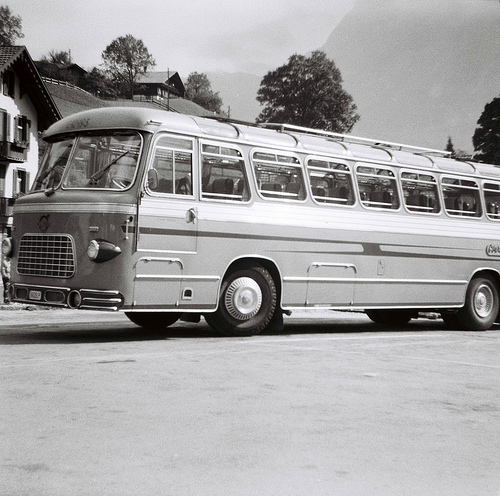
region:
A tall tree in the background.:
[256, 47, 361, 138]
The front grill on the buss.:
[15, 232, 77, 282]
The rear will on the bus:
[465, 275, 499, 333]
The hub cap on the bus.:
[224, 275, 263, 322]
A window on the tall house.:
[13, 112, 33, 151]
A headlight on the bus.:
[86, 239, 99, 263]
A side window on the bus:
[199, 137, 251, 204]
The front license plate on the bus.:
[27, 289, 43, 302]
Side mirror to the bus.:
[146, 170, 159, 190]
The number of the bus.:
[63, 117, 91, 128]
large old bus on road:
[1, 105, 498, 337]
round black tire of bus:
[211, 260, 278, 340]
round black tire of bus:
[443, 275, 498, 332]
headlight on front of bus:
[84, 237, 100, 261]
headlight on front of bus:
[0, 235, 15, 260]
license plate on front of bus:
[27, 288, 45, 303]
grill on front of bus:
[13, 232, 78, 279]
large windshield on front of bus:
[30, 137, 142, 189]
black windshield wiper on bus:
[89, 147, 127, 183]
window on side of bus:
[250, 149, 309, 202]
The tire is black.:
[214, 252, 283, 327]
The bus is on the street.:
[14, 113, 497, 370]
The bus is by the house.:
[4, 98, 495, 342]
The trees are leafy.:
[90, 33, 499, 158]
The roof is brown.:
[3, 45, 215, 113]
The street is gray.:
[7, 323, 484, 495]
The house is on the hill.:
[38, 40, 199, 119]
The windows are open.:
[118, 131, 496, 221]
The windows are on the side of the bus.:
[119, 130, 495, 222]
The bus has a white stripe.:
[135, 190, 497, 257]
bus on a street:
[2, 101, 494, 338]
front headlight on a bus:
[80, 233, 125, 269]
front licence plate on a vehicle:
[24, 287, 46, 306]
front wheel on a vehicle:
[202, 254, 286, 343]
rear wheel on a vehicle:
[438, 269, 498, 336]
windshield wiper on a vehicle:
[86, 147, 133, 191]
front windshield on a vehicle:
[23, 126, 145, 196]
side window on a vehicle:
[250, 144, 311, 206]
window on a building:
[9, 110, 34, 152]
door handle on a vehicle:
[182, 204, 204, 229]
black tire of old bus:
[210, 253, 287, 336]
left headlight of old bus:
[82, 234, 129, 269]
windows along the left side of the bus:
[142, 125, 498, 230]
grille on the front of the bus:
[11, 228, 79, 281]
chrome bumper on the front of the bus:
[5, 280, 123, 313]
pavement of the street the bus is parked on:
[8, 340, 485, 482]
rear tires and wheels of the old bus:
[442, 267, 497, 331]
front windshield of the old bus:
[25, 138, 142, 195]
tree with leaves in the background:
[255, 94, 360, 126]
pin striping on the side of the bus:
[125, 223, 499, 268]